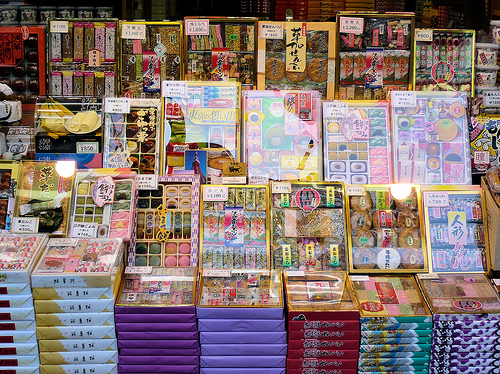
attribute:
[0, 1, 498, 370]
stand — red, selling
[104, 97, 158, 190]
magazines — circle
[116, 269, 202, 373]
book — purple, white, gray, black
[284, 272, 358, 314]
cover — yellow, red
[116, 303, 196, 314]
paper — purple, puple, red, gold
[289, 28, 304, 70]
writing — black, yellow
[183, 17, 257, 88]
gift box — pink, green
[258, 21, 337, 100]
gift box — black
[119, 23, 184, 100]
package — purple, blue, red, set, black, white, lavender, green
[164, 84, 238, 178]
card — white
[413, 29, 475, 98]
box — plastic, pink